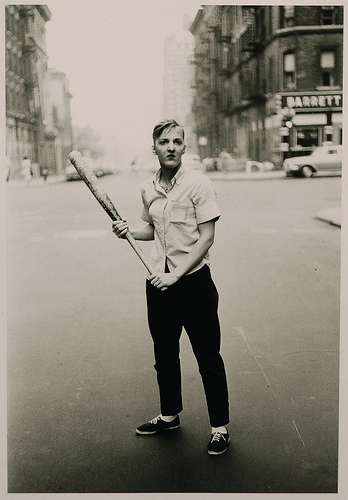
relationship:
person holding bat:
[63, 102, 283, 467] [79, 151, 164, 289]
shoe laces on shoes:
[148, 414, 225, 443] [136, 414, 229, 455]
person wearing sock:
[136, 118, 234, 460] [159, 413, 179, 421]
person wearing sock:
[136, 118, 234, 460] [211, 425, 227, 433]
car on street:
[282, 144, 341, 174] [211, 181, 342, 300]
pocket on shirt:
[164, 187, 190, 221] [92, 156, 226, 299]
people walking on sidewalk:
[18, 156, 47, 181] [0, 168, 70, 200]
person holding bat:
[136, 118, 234, 460] [53, 135, 170, 293]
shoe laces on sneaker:
[210, 432, 227, 446] [206, 425, 230, 456]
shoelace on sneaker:
[143, 408, 175, 443] [134, 414, 182, 437]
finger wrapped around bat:
[118, 227, 129, 239] [66, 147, 165, 293]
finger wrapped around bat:
[104, 211, 125, 225] [66, 147, 165, 293]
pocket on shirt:
[168, 199, 188, 224] [102, 170, 235, 268]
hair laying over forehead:
[151, 118, 186, 144] [158, 125, 182, 137]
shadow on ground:
[7, 426, 336, 491] [2, 166, 337, 491]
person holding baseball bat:
[136, 118, 234, 460] [69, 150, 157, 271]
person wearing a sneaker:
[136, 118, 234, 460] [120, 392, 176, 441]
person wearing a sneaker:
[136, 118, 234, 460] [195, 428, 245, 469]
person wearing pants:
[136, 118, 234, 460] [126, 261, 274, 394]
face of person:
[156, 123, 183, 167] [136, 118, 234, 460]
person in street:
[136, 118, 234, 460] [12, 109, 344, 482]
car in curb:
[282, 143, 341, 179] [204, 169, 340, 181]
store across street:
[265, 94, 343, 167] [215, 180, 340, 492]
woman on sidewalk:
[19, 152, 35, 183] [8, 169, 66, 187]